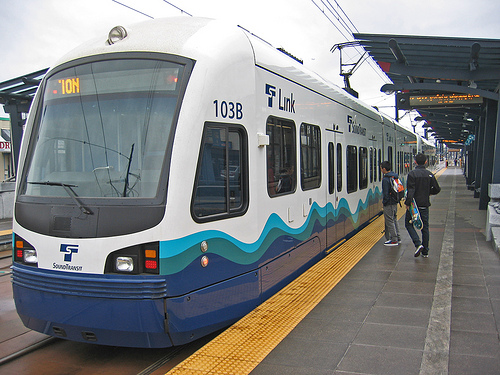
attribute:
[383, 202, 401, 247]
pants — grey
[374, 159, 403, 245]
person — standing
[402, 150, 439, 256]
person — standing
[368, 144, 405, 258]
boy — wearing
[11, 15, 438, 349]
train — white, blue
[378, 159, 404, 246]
man — wearing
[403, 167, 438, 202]
jacket — black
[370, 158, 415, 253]
boy — wearing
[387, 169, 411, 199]
backpack — orange, white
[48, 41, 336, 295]
train — blue, white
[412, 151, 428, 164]
hair — dark